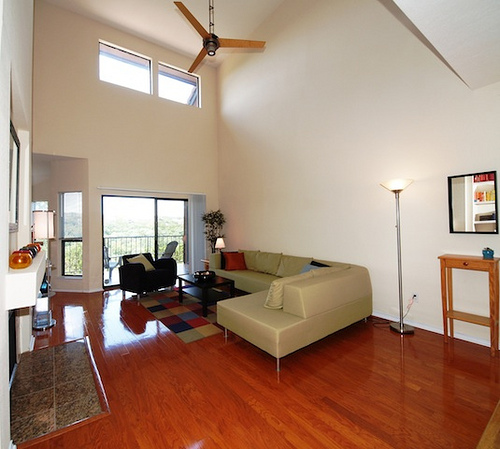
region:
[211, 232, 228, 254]
a table lamp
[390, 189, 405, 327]
a lamp pole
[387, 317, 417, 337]
the base of a floor lamp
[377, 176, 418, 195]
the top of a floor lamp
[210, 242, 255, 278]
a red pillow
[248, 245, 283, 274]
a tan cushion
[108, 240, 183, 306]
a black chair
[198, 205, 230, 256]
a plant in the corner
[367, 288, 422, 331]
a power cord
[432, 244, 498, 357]
a wooden table by the lamp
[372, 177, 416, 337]
a silver and white floor lamp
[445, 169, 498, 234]
a mirror hanging on the wall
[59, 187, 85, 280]
a window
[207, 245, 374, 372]
a beige sofa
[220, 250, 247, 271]
a red pillow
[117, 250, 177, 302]
a black chair with a beige pillow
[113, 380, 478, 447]
hardwood flooring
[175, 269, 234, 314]
a black coffee table can be seen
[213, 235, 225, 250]
a white lampshade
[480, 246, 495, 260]
a blue container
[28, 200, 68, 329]
floor lamp in living room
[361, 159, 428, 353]
silver floor lamp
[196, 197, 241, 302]
potted floor plant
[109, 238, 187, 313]
black one seater couch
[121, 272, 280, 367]
colorful rug on the floor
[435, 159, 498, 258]
black framed square mirror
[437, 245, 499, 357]
brown wooden console table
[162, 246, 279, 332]
black center table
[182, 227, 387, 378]
sectional couch in living room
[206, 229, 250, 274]
small lamp on table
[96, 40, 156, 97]
a window in the house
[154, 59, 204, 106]
a window in the house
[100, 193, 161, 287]
a window in the house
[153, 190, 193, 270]
a window in the house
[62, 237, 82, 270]
a window in the house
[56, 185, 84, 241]
a window in the house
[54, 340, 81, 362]
a tile on the floor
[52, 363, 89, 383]
a tile on the floor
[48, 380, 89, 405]
a tile on the floor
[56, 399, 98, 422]
a tile on the floor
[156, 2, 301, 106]
brown wooden ceiling fan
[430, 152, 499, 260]
black rimmed square mirror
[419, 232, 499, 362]
small brown wooden table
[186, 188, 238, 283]
floor potted plant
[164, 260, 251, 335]
black center table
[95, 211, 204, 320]
black one seater couch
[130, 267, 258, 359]
colorful rug in living room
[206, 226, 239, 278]
small table lamp